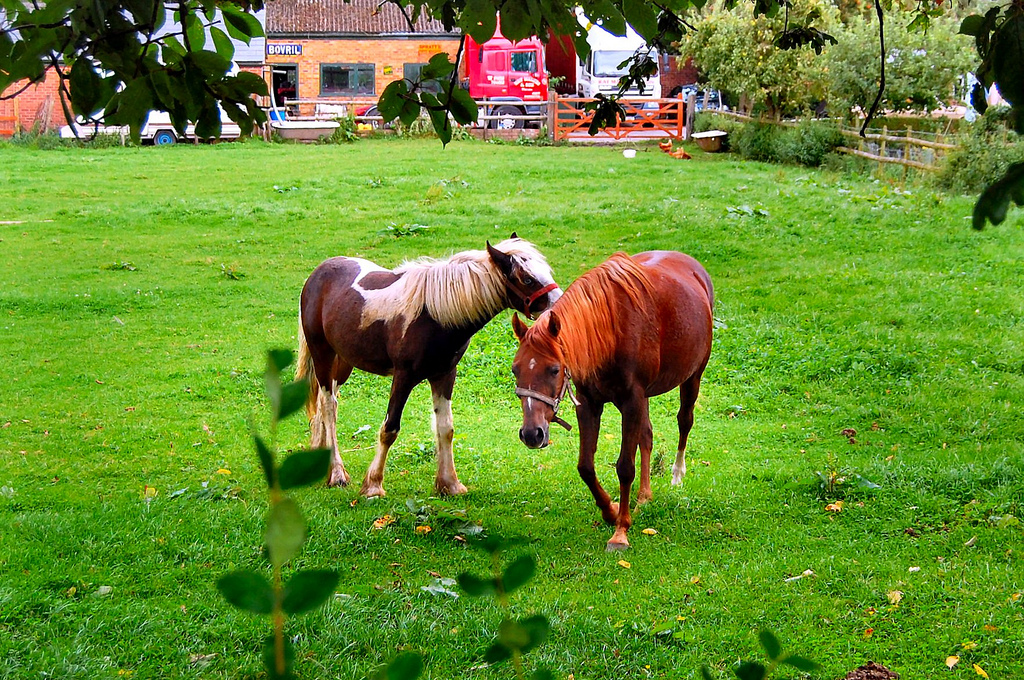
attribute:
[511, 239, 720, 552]
horse — brown, red, enclosed, standing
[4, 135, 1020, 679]
grass — lush, grassy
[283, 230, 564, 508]
horse — spotted, dark brown, brown, cream, white, chestnut, chestnut colored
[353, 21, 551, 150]
truck — red, large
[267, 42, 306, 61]
sign — blue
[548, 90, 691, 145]
gate — red, wooden, orange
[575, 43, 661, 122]
truck — white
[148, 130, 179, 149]
tire — blue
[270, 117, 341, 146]
trough — white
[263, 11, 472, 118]
building — brick, tan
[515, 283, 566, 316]
halter — red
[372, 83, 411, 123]
leaves — green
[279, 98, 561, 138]
fence — wooden